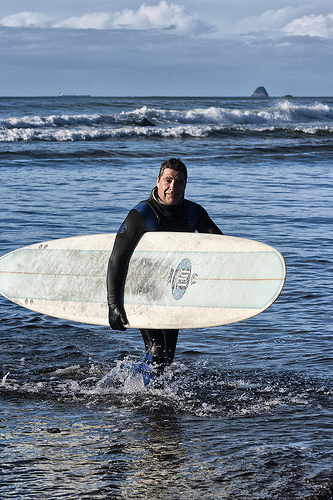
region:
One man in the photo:
[0, 130, 304, 408]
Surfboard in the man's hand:
[0, 220, 289, 330]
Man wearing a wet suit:
[93, 146, 231, 391]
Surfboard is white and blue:
[0, 221, 314, 343]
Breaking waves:
[0, 106, 327, 161]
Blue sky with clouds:
[5, 5, 331, 101]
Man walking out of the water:
[34, 126, 267, 430]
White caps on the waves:
[195, 106, 326, 125]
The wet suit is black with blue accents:
[102, 186, 220, 380]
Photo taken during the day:
[0, 11, 318, 496]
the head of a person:
[153, 156, 190, 205]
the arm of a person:
[100, 202, 148, 307]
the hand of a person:
[105, 298, 129, 334]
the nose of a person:
[168, 177, 177, 191]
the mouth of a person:
[162, 189, 177, 197]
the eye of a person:
[161, 176, 170, 184]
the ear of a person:
[154, 174, 161, 189]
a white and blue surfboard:
[0, 228, 288, 331]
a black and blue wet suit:
[101, 185, 230, 365]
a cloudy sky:
[0, 0, 332, 97]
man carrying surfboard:
[0, 157, 294, 369]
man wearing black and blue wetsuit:
[104, 156, 221, 391]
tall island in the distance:
[250, 83, 268, 97]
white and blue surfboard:
[1, 234, 285, 331]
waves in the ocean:
[1, 98, 332, 158]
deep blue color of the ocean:
[3, 94, 331, 498]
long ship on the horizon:
[53, 91, 92, 97]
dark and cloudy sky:
[1, 0, 332, 95]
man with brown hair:
[156, 157, 188, 203]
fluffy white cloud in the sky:
[3, 0, 212, 39]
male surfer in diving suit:
[87, 143, 236, 380]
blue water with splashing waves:
[1, 383, 332, 452]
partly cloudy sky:
[1, 2, 254, 85]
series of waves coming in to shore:
[0, 10, 332, 158]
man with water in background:
[149, 147, 198, 210]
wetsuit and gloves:
[106, 149, 229, 378]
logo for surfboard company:
[159, 249, 209, 307]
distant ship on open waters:
[36, 49, 126, 107]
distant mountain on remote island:
[227, 70, 327, 119]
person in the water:
[68, 139, 280, 333]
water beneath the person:
[227, 370, 277, 417]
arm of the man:
[86, 214, 171, 302]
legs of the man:
[115, 335, 194, 398]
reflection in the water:
[94, 407, 195, 475]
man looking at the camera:
[107, 147, 243, 269]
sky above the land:
[122, 45, 176, 82]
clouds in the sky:
[123, 7, 189, 35]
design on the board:
[161, 251, 200, 300]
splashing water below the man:
[93, 348, 196, 416]